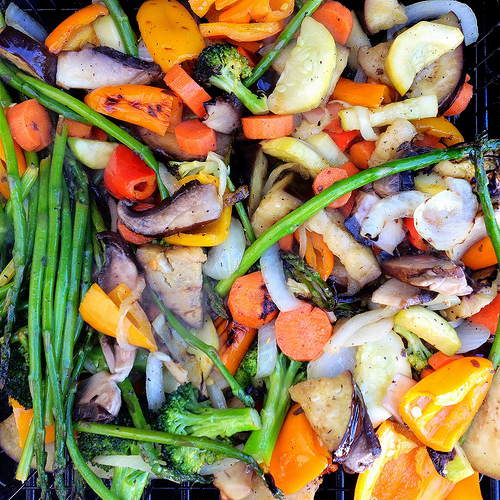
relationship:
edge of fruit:
[289, 441, 318, 481] [264, 406, 333, 496]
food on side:
[410, 179, 474, 247] [403, 50, 492, 497]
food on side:
[7, 94, 49, 147] [1, 0, 175, 497]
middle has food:
[197, 177, 307, 302] [208, 209, 292, 288]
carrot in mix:
[272, 305, 328, 364] [0, 2, 498, 497]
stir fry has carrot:
[8, 0, 495, 497] [274, 301, 332, 361]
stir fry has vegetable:
[8, 0, 495, 497] [155, 379, 265, 475]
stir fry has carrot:
[8, 0, 495, 497] [241, 115, 293, 140]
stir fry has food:
[8, 0, 495, 497] [215, 139, 500, 300]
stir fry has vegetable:
[8, 0, 495, 497] [130, 2, 207, 73]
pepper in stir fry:
[398, 357, 495, 452] [8, 0, 495, 497]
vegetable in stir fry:
[136, 0, 207, 74] [8, 0, 495, 497]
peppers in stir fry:
[266, 404, 329, 494] [8, 0, 495, 497]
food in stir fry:
[77, 281, 156, 352] [8, 0, 495, 497]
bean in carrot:
[71, 422, 264, 486] [226, 271, 278, 330]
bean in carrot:
[18, 73, 162, 179] [226, 271, 278, 330]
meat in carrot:
[134, 243, 206, 335] [226, 271, 278, 330]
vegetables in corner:
[354, 419, 484, 500] [361, 392, 493, 495]